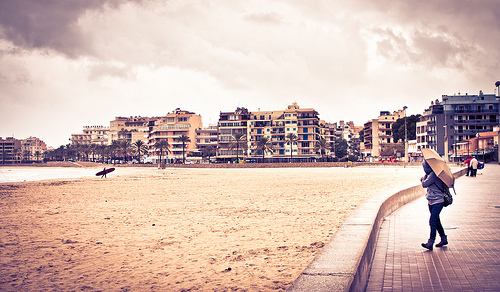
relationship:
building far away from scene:
[1, 135, 46, 167] [0, 0, 497, 289]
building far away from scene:
[45, 122, 105, 161] [0, 0, 497, 289]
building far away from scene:
[105, 108, 201, 161] [0, 0, 497, 289]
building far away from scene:
[193, 97, 336, 165] [0, 0, 497, 289]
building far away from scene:
[341, 102, 405, 164] [0, 0, 497, 289]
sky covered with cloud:
[1, 2, 498, 154] [1, 0, 121, 60]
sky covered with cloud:
[1, 2, 498, 154] [371, 27, 423, 67]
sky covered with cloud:
[1, 2, 498, 154] [406, 25, 474, 72]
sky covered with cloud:
[1, 2, 498, 154] [358, 0, 499, 85]